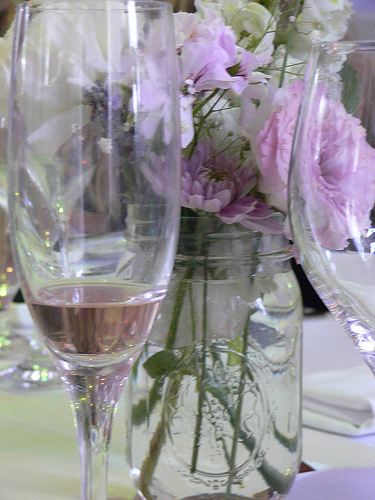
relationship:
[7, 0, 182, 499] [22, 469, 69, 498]
champagne glass on table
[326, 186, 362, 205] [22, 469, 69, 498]
wine glass on table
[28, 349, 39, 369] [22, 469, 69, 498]
wine glass on table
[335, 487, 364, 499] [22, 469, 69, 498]
tablecloth on table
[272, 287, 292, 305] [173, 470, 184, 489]
bottle with water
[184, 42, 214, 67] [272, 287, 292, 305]
flower in bottle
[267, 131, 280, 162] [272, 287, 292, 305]
flower in bottle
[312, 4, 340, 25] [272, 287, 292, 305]
flower in bottle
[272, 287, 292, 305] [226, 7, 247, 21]
bottle with flower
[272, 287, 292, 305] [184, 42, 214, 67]
bottle with flower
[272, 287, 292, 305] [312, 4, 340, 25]
bottle with flower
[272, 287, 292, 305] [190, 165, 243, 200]
bottle with flower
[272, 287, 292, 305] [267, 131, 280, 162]
bottle with flower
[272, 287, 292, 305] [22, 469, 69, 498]
bottle on table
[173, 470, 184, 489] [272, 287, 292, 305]
water in bottle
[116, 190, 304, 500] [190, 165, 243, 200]
bottle has rose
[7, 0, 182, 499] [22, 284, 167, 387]
champagne glass with champagne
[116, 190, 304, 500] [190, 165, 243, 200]
bottle with flower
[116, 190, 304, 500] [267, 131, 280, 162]
bottle with flower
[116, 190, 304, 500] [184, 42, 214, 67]
bottle with flower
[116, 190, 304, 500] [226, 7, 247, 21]
bottle with flower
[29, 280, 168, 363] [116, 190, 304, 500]
champagne in bottle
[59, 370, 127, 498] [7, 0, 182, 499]
stem on champagne glass